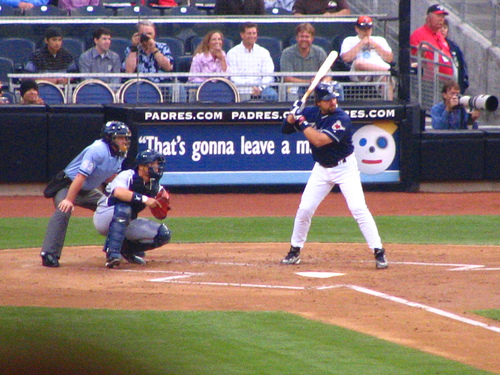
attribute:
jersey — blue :
[297, 105, 353, 166]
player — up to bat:
[280, 79, 388, 266]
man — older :
[408, 4, 452, 90]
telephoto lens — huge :
[452, 92, 498, 111]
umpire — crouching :
[34, 116, 133, 268]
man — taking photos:
[116, 18, 175, 76]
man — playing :
[278, 80, 389, 271]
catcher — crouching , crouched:
[89, 148, 171, 269]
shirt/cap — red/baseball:
[423, 1, 449, 18]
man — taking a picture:
[123, 17, 172, 79]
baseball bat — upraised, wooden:
[283, 47, 339, 111]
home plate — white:
[292, 262, 344, 280]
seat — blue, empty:
[197, 77, 242, 106]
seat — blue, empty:
[115, 76, 162, 104]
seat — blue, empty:
[69, 76, 116, 104]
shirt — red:
[407, 21, 455, 78]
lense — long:
[453, 92, 499, 114]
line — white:
[341, 281, 499, 332]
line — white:
[167, 272, 338, 286]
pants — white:
[289, 147, 382, 254]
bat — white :
[287, 46, 343, 110]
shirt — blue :
[286, 102, 357, 164]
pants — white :
[282, 164, 383, 253]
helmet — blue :
[310, 82, 336, 101]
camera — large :
[139, 32, 148, 42]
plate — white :
[295, 269, 345, 279]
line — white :
[347, 278, 498, 342]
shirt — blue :
[61, 135, 123, 190]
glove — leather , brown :
[145, 192, 174, 222]